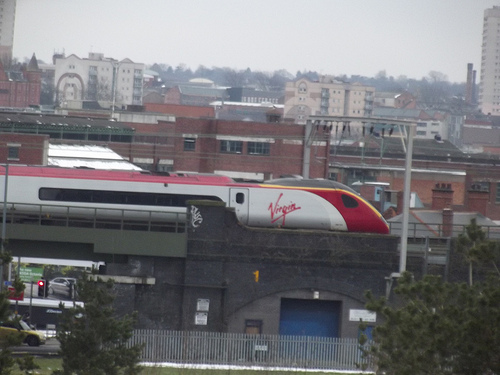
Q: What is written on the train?
A: Virgin.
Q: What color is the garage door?
A: Blue.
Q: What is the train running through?
A: A large city.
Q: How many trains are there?
A: One.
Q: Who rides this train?
A: Passengers travelling.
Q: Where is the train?
A: On a bridge.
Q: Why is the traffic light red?
A: To stop traffic.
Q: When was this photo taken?
A: During the daytime.